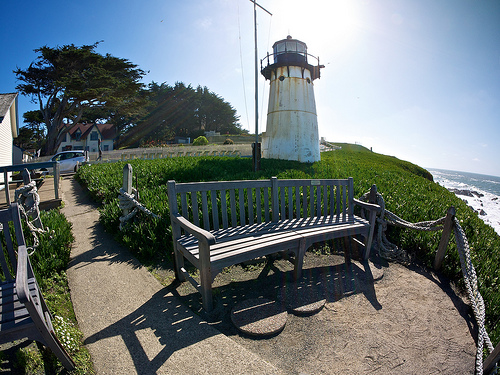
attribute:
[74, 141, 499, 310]
ground — green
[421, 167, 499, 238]
ocean — blue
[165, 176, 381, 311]
bench — large, wooden, wood, unpainted, vacant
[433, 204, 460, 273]
post — wood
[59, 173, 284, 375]
sidewalk — paved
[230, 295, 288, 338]
step — paving stone, round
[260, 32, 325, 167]
lighthouse — old, white, tall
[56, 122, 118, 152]
house — large, small, multistory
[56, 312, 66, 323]
flower — small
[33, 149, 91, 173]
car — silver, grey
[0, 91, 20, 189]
building — white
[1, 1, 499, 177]
sky — blue, clear, cloudless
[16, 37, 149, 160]
tree — green, leaning, leafy, large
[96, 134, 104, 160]
person — walking